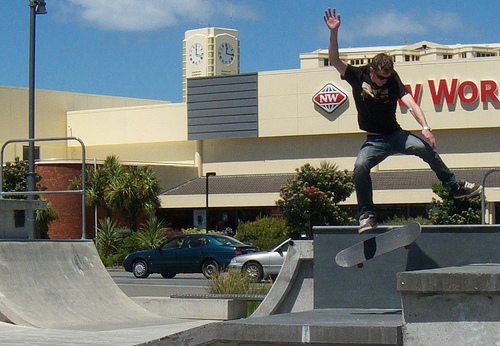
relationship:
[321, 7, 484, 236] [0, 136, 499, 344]
man in air at skate park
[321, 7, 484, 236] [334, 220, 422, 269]
man has a black skateboard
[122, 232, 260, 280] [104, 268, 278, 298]
car driving down street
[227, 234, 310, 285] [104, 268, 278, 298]
car driving down street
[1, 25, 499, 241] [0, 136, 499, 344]
buildings behind skate park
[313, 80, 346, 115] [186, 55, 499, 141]
sign on wall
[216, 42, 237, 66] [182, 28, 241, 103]
clock on tower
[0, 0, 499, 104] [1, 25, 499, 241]
cloudy blue sky above buildings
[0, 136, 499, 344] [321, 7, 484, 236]
skate park used by man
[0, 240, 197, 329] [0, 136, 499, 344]
half pipe in skate park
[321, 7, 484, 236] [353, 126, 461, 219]
man wearing jeans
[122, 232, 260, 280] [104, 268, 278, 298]
car on street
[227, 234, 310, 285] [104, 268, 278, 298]
car on street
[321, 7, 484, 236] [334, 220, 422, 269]
man jumping off black skateboard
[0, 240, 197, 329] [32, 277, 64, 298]
half pipe that grey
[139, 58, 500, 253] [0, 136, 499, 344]
buildings behind skate park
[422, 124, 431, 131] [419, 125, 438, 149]
silver watch on man's hand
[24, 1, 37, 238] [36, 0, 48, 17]
tall pole that has a light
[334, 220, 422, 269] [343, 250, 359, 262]
black skateboard that black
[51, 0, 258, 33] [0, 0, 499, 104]
cloud in cloudy blue sky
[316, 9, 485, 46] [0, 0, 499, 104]
cloud in cloudy blue sky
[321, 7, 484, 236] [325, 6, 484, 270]
man doing a trick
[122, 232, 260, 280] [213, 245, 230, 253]
car that dark green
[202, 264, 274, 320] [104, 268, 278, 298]
tall grass next to street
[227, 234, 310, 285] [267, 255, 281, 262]
car that silver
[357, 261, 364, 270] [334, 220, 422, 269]
red wheel on black skateboard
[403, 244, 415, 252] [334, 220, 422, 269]
red wheel on black skateboard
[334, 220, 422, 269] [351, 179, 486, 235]
black skateboard by man's feet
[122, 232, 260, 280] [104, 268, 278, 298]
car parked on street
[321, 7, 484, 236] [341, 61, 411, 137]
man wearing a black shirt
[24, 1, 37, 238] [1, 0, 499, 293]
tall pole in background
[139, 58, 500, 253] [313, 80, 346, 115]
buildings with a sign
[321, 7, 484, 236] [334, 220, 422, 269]
man doing jumps on a black skateboard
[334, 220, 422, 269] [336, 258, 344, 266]
black skateboard that grey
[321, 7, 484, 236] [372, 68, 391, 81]
man wearing sunglasses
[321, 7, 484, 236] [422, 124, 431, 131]
man wearing a silver watch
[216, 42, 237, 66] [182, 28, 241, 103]
clock on top of tower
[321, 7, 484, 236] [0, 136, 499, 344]
man jumps at skate park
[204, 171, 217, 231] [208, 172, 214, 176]
pole that black